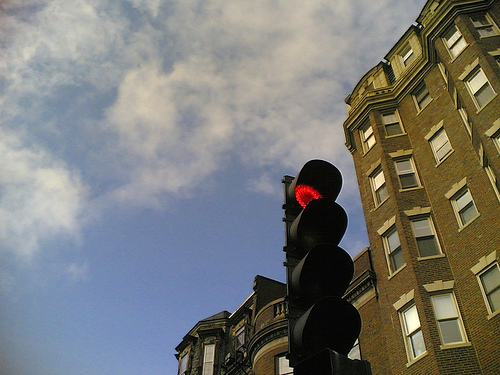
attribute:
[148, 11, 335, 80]
clouds — white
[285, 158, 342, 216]
light — red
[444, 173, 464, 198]
frame — tan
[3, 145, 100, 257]
clouds — white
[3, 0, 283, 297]
sky — blue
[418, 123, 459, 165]
window — tan 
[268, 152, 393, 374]
light — red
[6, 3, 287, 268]
sky — blue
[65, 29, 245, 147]
clouds — white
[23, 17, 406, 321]
sky — blue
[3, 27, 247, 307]
sky — blue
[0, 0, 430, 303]
clouds — white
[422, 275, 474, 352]
frame — tan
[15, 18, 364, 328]
sky — blue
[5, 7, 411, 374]
sky — blue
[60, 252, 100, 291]
cloud — white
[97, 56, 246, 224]
cloud — white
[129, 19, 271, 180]
clouds — white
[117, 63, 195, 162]
clouds — white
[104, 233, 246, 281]
sky — blue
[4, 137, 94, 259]
cloud — white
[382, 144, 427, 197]
frame — tan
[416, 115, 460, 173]
frame — tan